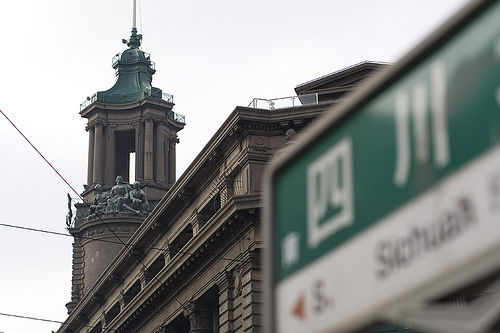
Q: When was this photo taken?
A: On a cloudy day.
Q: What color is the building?
A: Copper.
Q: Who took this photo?
A: A photographer.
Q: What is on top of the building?
A: A steeple.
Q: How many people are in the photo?
A: None.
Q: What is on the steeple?
A: Green statues.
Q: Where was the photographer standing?
A: Next to a street sign.